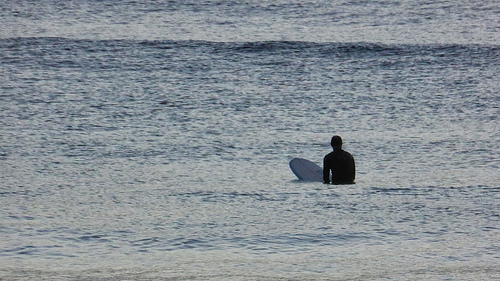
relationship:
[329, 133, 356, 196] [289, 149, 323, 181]
man on board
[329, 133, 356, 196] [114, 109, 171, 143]
man in ocean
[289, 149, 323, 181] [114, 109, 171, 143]
board in ocean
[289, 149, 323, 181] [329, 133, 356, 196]
board under man